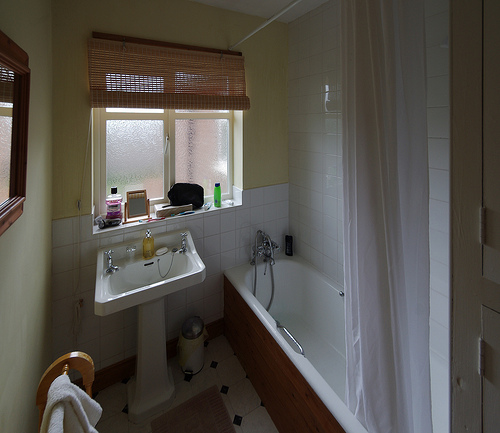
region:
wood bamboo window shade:
[85, 32, 251, 113]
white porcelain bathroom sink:
[97, 229, 205, 414]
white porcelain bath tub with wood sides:
[221, 250, 362, 430]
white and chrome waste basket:
[177, 313, 208, 378]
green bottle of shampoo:
[212, 182, 221, 207]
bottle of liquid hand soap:
[142, 228, 153, 258]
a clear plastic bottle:
[103, 188, 123, 227]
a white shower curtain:
[334, 4, 452, 420]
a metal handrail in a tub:
[273, 315, 308, 362]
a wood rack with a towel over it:
[39, 346, 90, 431]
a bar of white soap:
[153, 245, 171, 258]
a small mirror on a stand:
[123, 184, 155, 224]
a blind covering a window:
[80, 43, 258, 115]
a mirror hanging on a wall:
[0, 41, 37, 243]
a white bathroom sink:
[84, 222, 210, 319]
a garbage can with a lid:
[175, 311, 213, 381]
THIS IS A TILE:
[208, 342, 238, 362]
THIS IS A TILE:
[227, 385, 269, 415]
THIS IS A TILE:
[237, 421, 279, 431]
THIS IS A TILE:
[96, 372, 129, 414]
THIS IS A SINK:
[103, 228, 185, 310]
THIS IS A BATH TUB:
[256, 260, 352, 388]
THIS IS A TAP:
[101, 246, 116, 278]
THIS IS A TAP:
[173, 235, 188, 258]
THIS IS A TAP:
[260, 232, 282, 267]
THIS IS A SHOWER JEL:
[110, 182, 122, 224]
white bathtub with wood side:
[220, 245, 350, 431]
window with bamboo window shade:
[91, 32, 241, 233]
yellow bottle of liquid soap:
[142, 228, 154, 260]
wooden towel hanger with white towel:
[36, 352, 102, 431]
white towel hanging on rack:
[36, 373, 102, 430]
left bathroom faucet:
[104, 248, 121, 275]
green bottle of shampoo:
[211, 180, 221, 209]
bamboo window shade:
[84, 31, 252, 108]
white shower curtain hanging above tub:
[225, 1, 442, 431]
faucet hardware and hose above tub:
[224, 227, 347, 430]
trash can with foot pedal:
[175, 315, 207, 382]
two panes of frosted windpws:
[96, 115, 234, 215]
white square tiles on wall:
[53, 181, 290, 388]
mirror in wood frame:
[1, 27, 30, 233]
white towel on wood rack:
[37, 350, 100, 431]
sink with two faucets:
[94, 227, 207, 317]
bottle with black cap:
[104, 185, 124, 224]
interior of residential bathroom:
[1, 1, 497, 431]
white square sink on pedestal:
[94, 227, 206, 424]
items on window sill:
[88, 39, 250, 234]